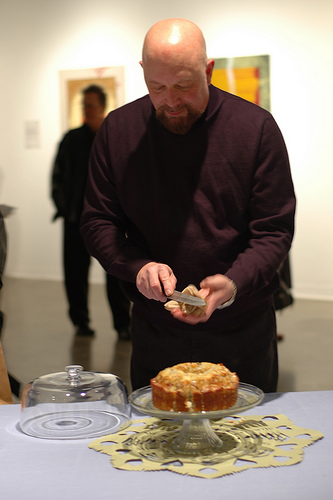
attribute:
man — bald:
[76, 16, 294, 389]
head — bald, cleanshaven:
[129, 16, 217, 131]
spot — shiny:
[166, 20, 185, 45]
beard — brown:
[158, 111, 199, 134]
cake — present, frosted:
[150, 359, 238, 412]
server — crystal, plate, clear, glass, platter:
[129, 381, 265, 450]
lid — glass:
[15, 362, 134, 440]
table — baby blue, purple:
[2, 390, 333, 499]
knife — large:
[166, 287, 206, 308]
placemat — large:
[88, 416, 327, 481]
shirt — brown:
[78, 89, 297, 309]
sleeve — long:
[227, 120, 297, 297]